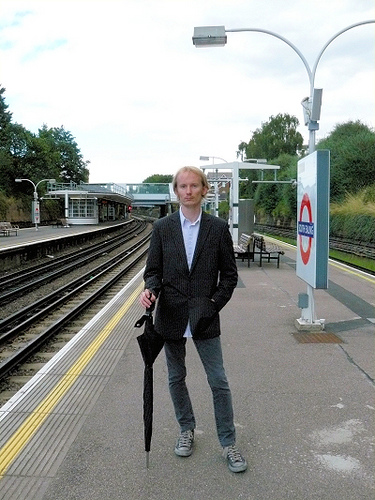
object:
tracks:
[1, 214, 164, 400]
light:
[191, 24, 227, 48]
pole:
[225, 18, 375, 99]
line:
[1, 277, 148, 475]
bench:
[230, 230, 259, 268]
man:
[137, 161, 258, 473]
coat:
[140, 209, 240, 343]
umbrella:
[133, 290, 169, 471]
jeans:
[163, 328, 235, 451]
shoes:
[172, 423, 197, 459]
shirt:
[175, 205, 207, 339]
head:
[170, 164, 208, 213]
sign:
[293, 148, 333, 292]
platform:
[0, 212, 374, 499]